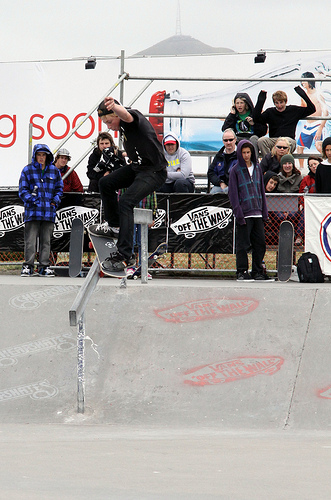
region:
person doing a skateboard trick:
[79, 87, 169, 278]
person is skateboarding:
[68, 95, 154, 276]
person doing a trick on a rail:
[88, 102, 184, 319]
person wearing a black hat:
[82, 83, 135, 113]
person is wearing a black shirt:
[119, 114, 165, 172]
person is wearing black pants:
[110, 167, 154, 254]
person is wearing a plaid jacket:
[16, 145, 59, 217]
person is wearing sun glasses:
[219, 133, 238, 144]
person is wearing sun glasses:
[272, 140, 290, 153]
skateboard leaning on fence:
[278, 217, 290, 285]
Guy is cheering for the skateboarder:
[253, 86, 313, 132]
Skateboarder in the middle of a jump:
[80, 96, 172, 280]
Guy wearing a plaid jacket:
[18, 144, 62, 225]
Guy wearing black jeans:
[20, 213, 54, 266]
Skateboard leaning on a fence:
[271, 214, 295, 285]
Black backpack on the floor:
[296, 250, 330, 280]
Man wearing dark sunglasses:
[219, 128, 235, 149]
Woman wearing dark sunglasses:
[272, 140, 289, 154]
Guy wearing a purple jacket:
[227, 137, 268, 222]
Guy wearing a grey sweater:
[160, 130, 197, 184]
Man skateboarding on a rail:
[60, 80, 166, 287]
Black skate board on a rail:
[77, 198, 128, 288]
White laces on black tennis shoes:
[86, 212, 118, 240]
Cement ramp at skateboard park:
[126, 288, 258, 408]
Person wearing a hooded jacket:
[226, 133, 265, 233]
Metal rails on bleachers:
[105, 70, 174, 122]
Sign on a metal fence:
[177, 198, 221, 267]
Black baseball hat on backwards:
[98, 93, 127, 127]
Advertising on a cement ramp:
[179, 341, 283, 404]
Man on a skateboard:
[86, 94, 169, 275]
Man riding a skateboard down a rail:
[80, 95, 169, 278]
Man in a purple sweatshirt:
[228, 137, 270, 280]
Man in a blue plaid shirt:
[18, 143, 64, 277]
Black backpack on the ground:
[294, 250, 325, 283]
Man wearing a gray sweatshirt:
[158, 129, 195, 193]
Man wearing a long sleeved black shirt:
[250, 83, 317, 140]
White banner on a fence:
[301, 193, 330, 274]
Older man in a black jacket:
[205, 125, 239, 195]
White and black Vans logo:
[167, 203, 231, 239]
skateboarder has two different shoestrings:
[90, 217, 125, 269]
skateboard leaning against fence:
[275, 221, 298, 282]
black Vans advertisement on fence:
[166, 193, 234, 254]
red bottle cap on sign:
[147, 89, 170, 145]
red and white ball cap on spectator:
[162, 132, 177, 147]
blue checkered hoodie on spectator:
[17, 136, 67, 224]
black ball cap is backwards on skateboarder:
[96, 97, 131, 117]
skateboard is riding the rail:
[87, 224, 129, 290]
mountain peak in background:
[131, 30, 236, 55]